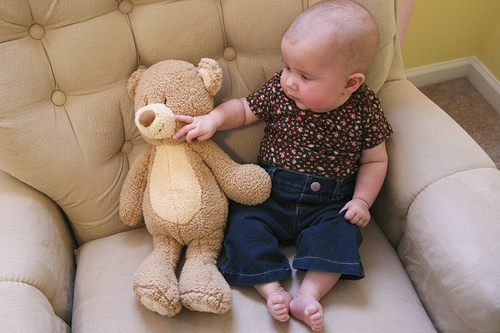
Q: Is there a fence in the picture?
A: No, there are no fences.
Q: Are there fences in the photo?
A: No, there are no fences.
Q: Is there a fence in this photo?
A: No, there are no fences.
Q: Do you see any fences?
A: No, there are no fences.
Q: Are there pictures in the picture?
A: No, there are no pictures.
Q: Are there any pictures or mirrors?
A: No, there are no pictures or mirrors.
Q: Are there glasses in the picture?
A: No, there are no glasses.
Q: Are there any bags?
A: No, there are no bags.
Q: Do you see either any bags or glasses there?
A: No, there are no bags or glasses.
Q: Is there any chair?
A: Yes, there is a chair.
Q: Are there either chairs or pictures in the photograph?
A: Yes, there is a chair.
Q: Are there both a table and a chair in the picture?
A: No, there is a chair but no tables.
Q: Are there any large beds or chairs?
A: Yes, there is a large chair.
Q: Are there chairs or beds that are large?
A: Yes, the chair is large.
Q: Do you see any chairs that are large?
A: Yes, there is a large chair.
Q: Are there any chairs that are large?
A: Yes, there is a chair that is large.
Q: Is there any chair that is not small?
A: Yes, there is a large chair.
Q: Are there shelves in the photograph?
A: No, there are no shelves.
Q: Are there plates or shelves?
A: No, there are no shelves or plates.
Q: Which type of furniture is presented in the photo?
A: The furniture is a chair.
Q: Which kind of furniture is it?
A: The piece of furniture is a chair.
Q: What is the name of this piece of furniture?
A: This is a chair.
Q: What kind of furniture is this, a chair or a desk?
A: This is a chair.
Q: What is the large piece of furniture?
A: The piece of furniture is a chair.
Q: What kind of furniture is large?
A: The furniture is a chair.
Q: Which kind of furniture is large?
A: The furniture is a chair.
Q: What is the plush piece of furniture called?
A: The piece of furniture is a chair.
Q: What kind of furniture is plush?
A: The furniture is a chair.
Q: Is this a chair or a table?
A: This is a chair.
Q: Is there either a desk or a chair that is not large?
A: No, there is a chair but it is large.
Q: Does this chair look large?
A: Yes, the chair is large.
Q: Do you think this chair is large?
A: Yes, the chair is large.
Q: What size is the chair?
A: The chair is large.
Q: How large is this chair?
A: The chair is large.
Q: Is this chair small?
A: No, the chair is large.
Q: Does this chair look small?
A: No, the chair is large.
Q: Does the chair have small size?
A: No, the chair is large.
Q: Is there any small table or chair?
A: No, there is a chair but it is large.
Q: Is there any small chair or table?
A: No, there is a chair but it is large.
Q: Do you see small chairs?
A: No, there is a chair but it is large.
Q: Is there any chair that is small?
A: No, there is a chair but it is large.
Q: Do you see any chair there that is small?
A: No, there is a chair but it is large.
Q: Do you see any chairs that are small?
A: No, there is a chair but it is large.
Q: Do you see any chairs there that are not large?
A: No, there is a chair but it is large.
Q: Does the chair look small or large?
A: The chair is large.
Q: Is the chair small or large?
A: The chair is large.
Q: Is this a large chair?
A: Yes, this is a large chair.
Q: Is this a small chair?
A: No, this is a large chair.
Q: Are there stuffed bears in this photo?
A: Yes, there is a stuffed bear.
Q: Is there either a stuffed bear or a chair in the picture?
A: Yes, there is a stuffed bear.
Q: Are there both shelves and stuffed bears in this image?
A: No, there is a stuffed bear but no shelves.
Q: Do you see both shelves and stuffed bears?
A: No, there is a stuffed bear but no shelves.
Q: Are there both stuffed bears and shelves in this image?
A: No, there is a stuffed bear but no shelves.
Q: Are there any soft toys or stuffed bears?
A: Yes, there is a soft stuffed bear.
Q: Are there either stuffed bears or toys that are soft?
A: Yes, the stuffed bear is soft.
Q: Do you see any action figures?
A: No, there are no action figures.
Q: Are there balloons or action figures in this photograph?
A: No, there are no action figures or balloons.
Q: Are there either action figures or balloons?
A: No, there are no action figures or balloons.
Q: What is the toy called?
A: The toy is a stuffed bear.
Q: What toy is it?
A: The toy is a stuffed bear.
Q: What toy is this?
A: This is a stuffed bear.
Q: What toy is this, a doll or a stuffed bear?
A: This is a stuffed bear.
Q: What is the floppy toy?
A: The toy is a stuffed bear.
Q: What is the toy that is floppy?
A: The toy is a stuffed bear.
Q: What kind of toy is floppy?
A: The toy is a stuffed bear.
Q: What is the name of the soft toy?
A: The toy is a stuffed bear.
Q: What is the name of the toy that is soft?
A: The toy is a stuffed bear.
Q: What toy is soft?
A: The toy is a stuffed bear.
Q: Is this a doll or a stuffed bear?
A: This is a stuffed bear.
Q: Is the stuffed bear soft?
A: Yes, the stuffed bear is soft.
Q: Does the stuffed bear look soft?
A: Yes, the stuffed bear is soft.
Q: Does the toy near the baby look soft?
A: Yes, the stuffed bear is soft.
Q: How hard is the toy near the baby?
A: The stuffed bear is soft.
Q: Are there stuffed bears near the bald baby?
A: Yes, there is a stuffed bear near the baby.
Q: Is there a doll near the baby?
A: No, there is a stuffed bear near the baby.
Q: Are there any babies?
A: Yes, there is a baby.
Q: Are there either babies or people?
A: Yes, there is a baby.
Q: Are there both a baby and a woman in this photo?
A: No, there is a baby but no women.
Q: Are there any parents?
A: No, there are no parents.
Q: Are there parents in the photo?
A: No, there are no parents.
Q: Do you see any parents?
A: No, there are no parents.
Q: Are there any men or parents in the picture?
A: No, there are no parents or men.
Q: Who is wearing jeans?
A: The baby is wearing jeans.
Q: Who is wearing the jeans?
A: The baby is wearing jeans.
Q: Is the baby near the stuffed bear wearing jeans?
A: Yes, the baby is wearing jeans.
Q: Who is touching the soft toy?
A: The baby is touching the stuffed bear.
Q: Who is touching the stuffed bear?
A: The baby is touching the stuffed bear.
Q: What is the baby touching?
A: The baby is touching the stuffed bear.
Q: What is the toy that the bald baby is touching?
A: The toy is a stuffed bear.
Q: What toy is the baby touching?
A: The baby is touching the stuffed bear.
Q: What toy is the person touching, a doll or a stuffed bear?
A: The baby is touching a stuffed bear.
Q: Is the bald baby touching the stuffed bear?
A: Yes, the baby is touching the stuffed bear.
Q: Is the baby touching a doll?
A: No, the baby is touching the stuffed bear.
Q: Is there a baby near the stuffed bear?
A: Yes, there is a baby near the stuffed bear.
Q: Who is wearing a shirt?
A: The baby is wearing a shirt.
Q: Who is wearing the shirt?
A: The baby is wearing a shirt.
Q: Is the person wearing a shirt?
A: Yes, the baby is wearing a shirt.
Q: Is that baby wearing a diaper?
A: No, the baby is wearing a shirt.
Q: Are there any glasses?
A: No, there are no glasses.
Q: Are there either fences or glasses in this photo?
A: No, there are no glasses or fences.